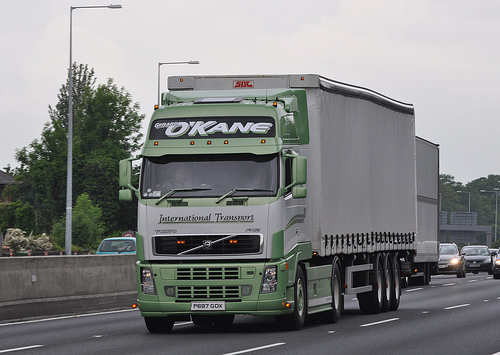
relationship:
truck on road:
[131, 69, 422, 335] [422, 284, 481, 353]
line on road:
[361, 310, 400, 334] [422, 284, 481, 353]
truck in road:
[131, 69, 422, 335] [422, 284, 481, 353]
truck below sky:
[131, 69, 422, 335] [234, 7, 415, 48]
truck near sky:
[131, 69, 422, 335] [234, 7, 415, 48]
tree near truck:
[52, 75, 131, 180] [131, 69, 422, 335]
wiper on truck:
[217, 178, 275, 208] [116, 73, 421, 335]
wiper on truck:
[153, 175, 210, 212] [116, 73, 421, 335]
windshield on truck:
[138, 151, 284, 202] [116, 73, 421, 335]